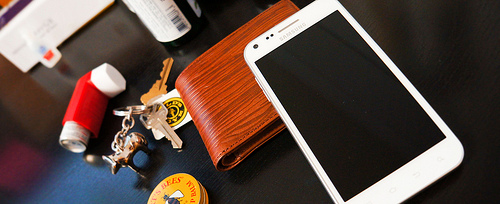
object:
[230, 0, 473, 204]
cellphone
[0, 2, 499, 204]
table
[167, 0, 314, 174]
wallet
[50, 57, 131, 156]
inhaler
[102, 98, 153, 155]
chain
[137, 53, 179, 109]
key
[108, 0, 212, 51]
bottle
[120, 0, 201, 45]
medication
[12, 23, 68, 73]
drops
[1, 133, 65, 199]
reflection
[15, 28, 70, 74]
bottle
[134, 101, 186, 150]
golds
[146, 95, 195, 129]
tag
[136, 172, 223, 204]
container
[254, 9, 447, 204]
screen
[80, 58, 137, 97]
cap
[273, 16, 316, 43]
samsung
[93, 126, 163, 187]
animal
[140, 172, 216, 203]
balm